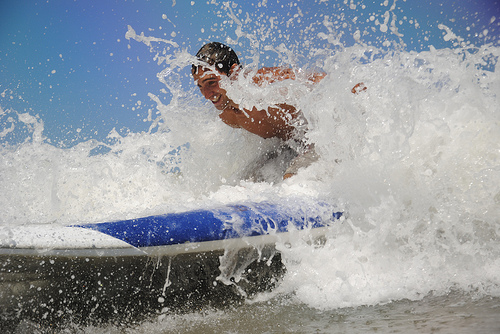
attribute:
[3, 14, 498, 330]
water — splashed, white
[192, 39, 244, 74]
hair — short, black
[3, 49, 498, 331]
water — white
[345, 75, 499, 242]
water — white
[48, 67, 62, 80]
water drop — white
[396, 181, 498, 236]
water — white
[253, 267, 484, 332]
water — white